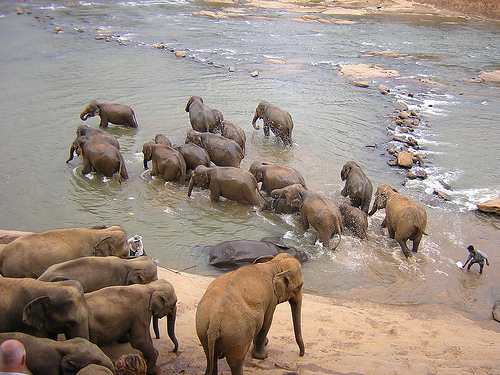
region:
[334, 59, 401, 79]
Large patch of sand in water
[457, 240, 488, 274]
Man taking some water wearing white shirt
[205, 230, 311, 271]
Large elephant is wet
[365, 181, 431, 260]
Large elephant walking behind elephant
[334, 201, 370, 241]
Small elephant next to large elephant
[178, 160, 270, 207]
Large elephant walking behind elephant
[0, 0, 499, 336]
Water is brown and murky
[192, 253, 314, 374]
Large elephant heading towards water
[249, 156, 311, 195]
Large elephant is wet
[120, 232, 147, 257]
Man in water wearing hat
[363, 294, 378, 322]
edge of a shore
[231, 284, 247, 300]
body of an elephant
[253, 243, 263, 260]
edge of an elephant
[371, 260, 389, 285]
part of a river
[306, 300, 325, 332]
edge of a shore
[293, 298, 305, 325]
part of a trunk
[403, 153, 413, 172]
edge of a rock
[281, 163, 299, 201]
tail of an elephant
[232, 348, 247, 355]
leg of an elephant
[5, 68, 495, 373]
many elephants color brown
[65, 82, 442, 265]
elephants are in the water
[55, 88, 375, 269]
elephants are wet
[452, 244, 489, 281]
a person in the water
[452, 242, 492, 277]
person holding a white container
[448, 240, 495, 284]
person filling a white container with water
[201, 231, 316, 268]
elephant is bathing in the water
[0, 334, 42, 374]
head of a person behind elephant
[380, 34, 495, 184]
stones in middle of the river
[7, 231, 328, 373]
elephants on the shore of a river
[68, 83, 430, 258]
group of elephants in water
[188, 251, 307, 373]
elephant standing on the bank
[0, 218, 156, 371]
elephants huddled together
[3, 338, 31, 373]
a mans head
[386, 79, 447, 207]
medium sized stones in the water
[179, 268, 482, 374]
sandy bank near the water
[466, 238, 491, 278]
man standing in the water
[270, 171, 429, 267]
elephants splashing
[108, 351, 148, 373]
top of a persons head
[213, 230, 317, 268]
a dark brown object in the water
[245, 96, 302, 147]
elephant walking through the water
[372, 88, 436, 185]
water rippling through the rocks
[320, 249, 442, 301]
muddy water in river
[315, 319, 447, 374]
sand on beach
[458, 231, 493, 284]
man in long sleeve shirt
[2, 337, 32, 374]
man with bald head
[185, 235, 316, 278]
elephant under water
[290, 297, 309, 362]
elephant's long grey trunk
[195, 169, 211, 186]
large grey ear on head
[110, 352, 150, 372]
woman with frosted hair